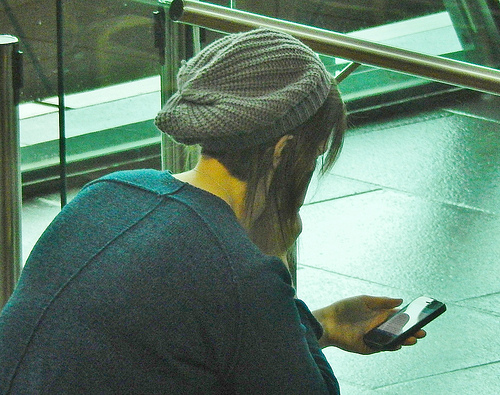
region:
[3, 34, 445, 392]
a girl texting on her cell phone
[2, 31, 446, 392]
a girl socializes on her cell phone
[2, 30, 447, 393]
a girl holding an apple iphone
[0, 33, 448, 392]
a girl passing time browsing her cell phone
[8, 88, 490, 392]
a gray ceramic tile floor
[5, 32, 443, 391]
a woman wears a gray knit hat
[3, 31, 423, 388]
a woman wears a grayish blue sweater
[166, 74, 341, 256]
a hairstyle with long hair in front and short hair in back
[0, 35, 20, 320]
a metal pole used to block passage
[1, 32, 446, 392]
a woman reading on her iphone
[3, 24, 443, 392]
woman looking at cell phone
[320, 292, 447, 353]
cell phone in hand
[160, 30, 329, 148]
knit cap on head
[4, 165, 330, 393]
back of gray sweater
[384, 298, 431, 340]
reflection on phone screen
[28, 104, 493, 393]
tile surface of floor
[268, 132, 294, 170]
ear poking out of hair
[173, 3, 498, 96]
tilted metal pole behind woman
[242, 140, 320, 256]
long strands of brown hair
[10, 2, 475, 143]
reflection on glass window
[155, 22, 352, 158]
grey beanie of person's head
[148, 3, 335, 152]
woman wearing a beanie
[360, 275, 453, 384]
woman looking at cellphone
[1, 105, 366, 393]
woman wearing a grey sweater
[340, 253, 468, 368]
black phone in hand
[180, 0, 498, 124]
metal pole in front of woman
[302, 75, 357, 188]
woman's bangs in face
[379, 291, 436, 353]
screen of black cellphone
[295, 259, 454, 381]
A person holding a cellphone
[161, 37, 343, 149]
Woman is wearing a hat.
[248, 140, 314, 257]
A hand on the side of face.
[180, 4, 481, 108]
A railing in front of the person.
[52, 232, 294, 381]
The peson is wearing a blue shirt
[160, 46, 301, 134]
The hat is gray.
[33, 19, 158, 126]
Glass window on the side.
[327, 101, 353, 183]
A piece of hair on forehead.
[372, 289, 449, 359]
The phone is black.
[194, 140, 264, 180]
Hair is short in the back.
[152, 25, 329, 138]
Brown knit hat on head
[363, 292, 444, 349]
Cell phone in man's hand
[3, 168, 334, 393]
Dark gray shirt on man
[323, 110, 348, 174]
Brown hair hanging in man's face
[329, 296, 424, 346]
Man's hand holding phone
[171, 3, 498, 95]
Shiny metal hand rail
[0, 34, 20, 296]
Metal post in floor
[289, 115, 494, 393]
Shiny white tiled floor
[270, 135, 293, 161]
Man's ear on head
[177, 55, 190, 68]
Tuft of yarn on hat